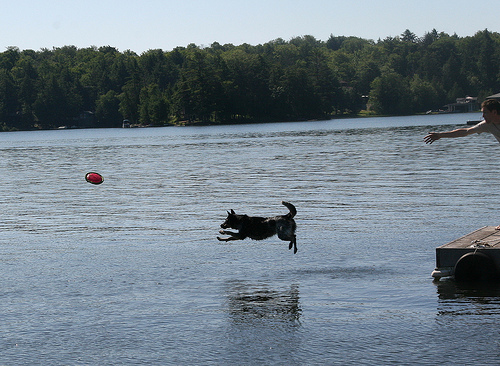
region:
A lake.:
[1, 109, 498, 364]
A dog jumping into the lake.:
[205, 197, 315, 257]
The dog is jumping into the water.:
[202, 192, 309, 253]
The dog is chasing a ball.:
[86, 165, 301, 258]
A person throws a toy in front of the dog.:
[409, 92, 498, 187]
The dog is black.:
[203, 194, 313, 251]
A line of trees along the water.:
[5, 20, 498, 132]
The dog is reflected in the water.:
[209, 270, 309, 334]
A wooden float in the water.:
[438, 213, 498, 275]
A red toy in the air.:
[74, 164, 106, 186]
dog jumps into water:
[210, 191, 316, 261]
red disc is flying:
[82, 164, 127, 193]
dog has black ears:
[176, 189, 238, 226]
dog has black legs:
[197, 229, 234, 252]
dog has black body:
[247, 202, 297, 231]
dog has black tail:
[252, 190, 304, 232]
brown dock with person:
[420, 192, 492, 265]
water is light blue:
[212, 249, 341, 356]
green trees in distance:
[5, 42, 482, 129]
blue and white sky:
[165, 2, 272, 44]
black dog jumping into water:
[206, 190, 307, 257]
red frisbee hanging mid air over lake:
[83, 164, 105, 186]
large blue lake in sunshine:
[7, 105, 499, 358]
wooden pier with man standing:
[433, 223, 498, 304]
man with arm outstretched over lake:
[422, 94, 496, 184]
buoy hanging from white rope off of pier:
[427, 247, 498, 290]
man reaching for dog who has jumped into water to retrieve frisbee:
[79, 90, 499, 269]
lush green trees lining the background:
[3, 20, 498, 129]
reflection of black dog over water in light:
[131, 239, 439, 332]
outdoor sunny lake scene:
[5, 0, 497, 360]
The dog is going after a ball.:
[77, 170, 107, 185]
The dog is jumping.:
[207, 198, 301, 258]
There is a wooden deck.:
[427, 221, 497, 293]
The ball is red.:
[83, 170, 104, 185]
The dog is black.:
[215, 194, 304, 256]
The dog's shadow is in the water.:
[220, 274, 305, 331]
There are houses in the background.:
[414, 92, 487, 112]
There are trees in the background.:
[1, 26, 498, 118]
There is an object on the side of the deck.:
[452, 248, 494, 292]